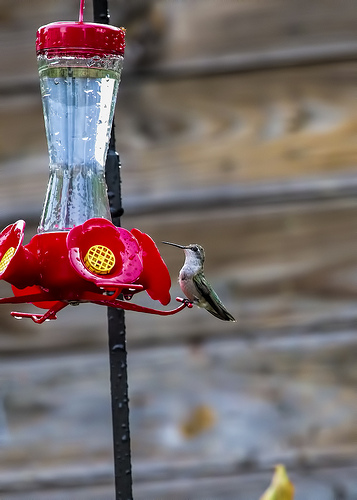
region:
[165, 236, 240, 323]
The bird is standing.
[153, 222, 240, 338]
It is a hummingbird.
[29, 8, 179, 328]
The feeder is hanging.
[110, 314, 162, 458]
The pole is black.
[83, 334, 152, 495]
The pole is wet.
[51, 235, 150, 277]
The feeder is red.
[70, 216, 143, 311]
The feeder looks like a flower.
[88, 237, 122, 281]
The middle is yellow.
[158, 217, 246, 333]
The bird is brown.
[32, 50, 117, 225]
Water is in the feeder.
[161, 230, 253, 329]
hummingbird on perch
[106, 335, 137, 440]
water drops on pole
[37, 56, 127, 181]
clear glass bird feeder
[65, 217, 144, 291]
flower shape on bird feeder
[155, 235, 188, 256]
long beak on bird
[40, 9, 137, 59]
red cap on feeder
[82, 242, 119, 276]
yellow screen on feeder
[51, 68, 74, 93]
water drops on glass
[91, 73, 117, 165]
light reflection on glass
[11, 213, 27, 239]
light reflection on plastic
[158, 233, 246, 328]
female ruby-throated hummingbird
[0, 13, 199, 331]
hummingbird feeder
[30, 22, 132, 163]
droplets of water on a hummingbird feeder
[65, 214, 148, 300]
feeding station on a hummingbird feeder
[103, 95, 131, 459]
pole supporting a hummingbird feeder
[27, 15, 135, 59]
cap of a hummingbird feeder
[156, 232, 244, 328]
hummingbird sitting on a feeder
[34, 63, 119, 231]
hummingbird food in a feeder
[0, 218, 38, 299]
flower shaped feeding station on a hummingbird feeder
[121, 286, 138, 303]
water drop hanging on a hummingbird feeder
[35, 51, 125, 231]
Clear middle of a hummingbird feeder.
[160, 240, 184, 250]
Long black beak of a hummingbird.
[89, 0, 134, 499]
Long thin black metal pole holding up a hummingbird feeder.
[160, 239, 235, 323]
Hummingbird on the side of a feeder.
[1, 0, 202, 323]
A clear, red and yellow hummingbird feeder.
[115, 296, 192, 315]
Little red plastic perch a hummingbird is on.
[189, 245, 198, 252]
Small black eye of a hummingbird.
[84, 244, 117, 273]
Plastic yellow middle of a red plastic flower to the left of a bird.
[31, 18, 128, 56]
Top red cap of a hummingbird feeder.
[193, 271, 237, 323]
Wings on the body of a hummingbird.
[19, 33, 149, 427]
wet bird feeder in foreground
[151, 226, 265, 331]
small hummingbird on feeder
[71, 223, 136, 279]
yellow mesh food dispensers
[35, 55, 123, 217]
clear water tank on feeder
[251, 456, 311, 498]
blurry yellow bird on ground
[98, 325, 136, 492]
stand of bird feeder with water on it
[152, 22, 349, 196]
blurry wooden wall in background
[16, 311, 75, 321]
water drops coming of feeder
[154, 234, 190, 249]
long black beak of hummingbird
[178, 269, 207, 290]
white feathers on hummingbird